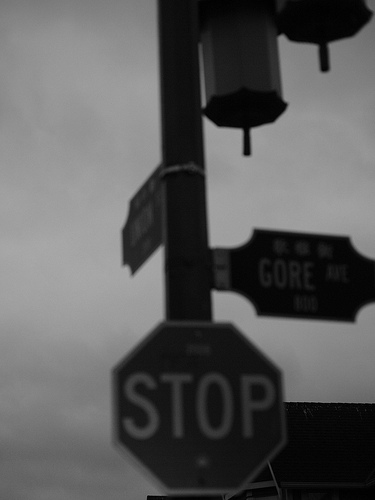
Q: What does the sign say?
A: Stop.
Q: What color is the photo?
A: Black and white.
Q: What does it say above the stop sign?
A: Gore.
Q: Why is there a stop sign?
A: For traffic.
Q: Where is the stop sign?
A: Attached to the pole.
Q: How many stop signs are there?
A: One.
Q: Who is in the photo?
A: No one.